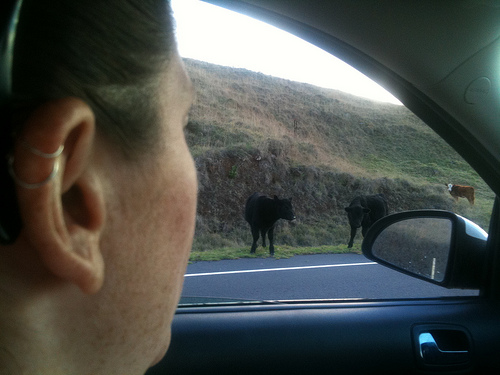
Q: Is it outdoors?
A: Yes, it is outdoors.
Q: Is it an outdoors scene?
A: Yes, it is outdoors.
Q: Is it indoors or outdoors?
A: It is outdoors.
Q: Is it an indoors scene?
A: No, it is outdoors.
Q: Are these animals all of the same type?
A: Yes, all the animals are cows.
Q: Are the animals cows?
A: Yes, all the animals are cows.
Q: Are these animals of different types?
A: No, all the animals are cows.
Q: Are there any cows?
A: Yes, there is a cow.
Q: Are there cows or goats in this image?
A: Yes, there is a cow.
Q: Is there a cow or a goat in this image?
A: Yes, there is a cow.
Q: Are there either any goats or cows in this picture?
A: Yes, there is a cow.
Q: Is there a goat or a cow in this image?
A: Yes, there is a cow.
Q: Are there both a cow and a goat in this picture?
A: No, there is a cow but no goats.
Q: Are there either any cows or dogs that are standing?
A: Yes, the cow is standing.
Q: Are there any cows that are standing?
A: Yes, there is a cow that is standing.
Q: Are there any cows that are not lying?
A: Yes, there is a cow that is standing.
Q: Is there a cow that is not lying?
A: Yes, there is a cow that is standing.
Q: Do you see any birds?
A: No, there are no birds.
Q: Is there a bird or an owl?
A: No, there are no birds or owls.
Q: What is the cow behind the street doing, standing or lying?
A: The cow is standing.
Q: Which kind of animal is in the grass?
A: The animal is a cow.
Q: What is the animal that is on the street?
A: The animal is a cow.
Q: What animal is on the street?
A: The animal is a cow.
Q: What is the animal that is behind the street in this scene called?
A: The animal is a cow.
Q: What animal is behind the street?
A: The animal is a cow.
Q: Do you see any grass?
A: Yes, there is grass.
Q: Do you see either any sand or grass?
A: Yes, there is grass.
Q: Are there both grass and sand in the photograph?
A: No, there is grass but no sand.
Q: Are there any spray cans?
A: No, there are no spray cans.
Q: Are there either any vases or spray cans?
A: No, there are no spray cans or vases.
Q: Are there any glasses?
A: No, there are no glasses.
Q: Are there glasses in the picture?
A: No, there are no glasses.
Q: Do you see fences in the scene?
A: No, there are no fences.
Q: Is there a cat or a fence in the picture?
A: No, there are no fences or cats.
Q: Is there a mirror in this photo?
A: Yes, there is a mirror.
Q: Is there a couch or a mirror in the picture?
A: Yes, there is a mirror.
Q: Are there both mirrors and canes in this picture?
A: No, there is a mirror but no canes.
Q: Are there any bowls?
A: No, there are no bowls.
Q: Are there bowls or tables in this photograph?
A: No, there are no bowls or tables.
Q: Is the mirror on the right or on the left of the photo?
A: The mirror is on the right of the image.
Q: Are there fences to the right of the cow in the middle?
A: No, there is a mirror to the right of the cow.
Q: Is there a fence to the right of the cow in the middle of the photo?
A: No, there is a mirror to the right of the cow.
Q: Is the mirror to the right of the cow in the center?
A: Yes, the mirror is to the right of the cow.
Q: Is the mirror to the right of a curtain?
A: No, the mirror is to the right of the cow.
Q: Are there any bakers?
A: No, there are no bakers.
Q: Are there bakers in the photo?
A: No, there are no bakers.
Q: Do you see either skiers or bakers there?
A: No, there are no bakers or skiers.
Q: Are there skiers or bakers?
A: No, there are no bakers or skiers.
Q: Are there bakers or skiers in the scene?
A: No, there are no bakers or skiers.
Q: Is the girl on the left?
A: Yes, the girl is on the left of the image.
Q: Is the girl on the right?
A: No, the girl is on the left of the image.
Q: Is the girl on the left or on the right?
A: The girl is on the left of the image.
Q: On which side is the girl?
A: The girl is on the left of the image.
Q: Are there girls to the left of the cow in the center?
A: Yes, there is a girl to the left of the cow.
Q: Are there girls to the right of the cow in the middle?
A: No, the girl is to the left of the cow.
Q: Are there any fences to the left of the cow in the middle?
A: No, there is a girl to the left of the cow.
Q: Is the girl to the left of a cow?
A: Yes, the girl is to the left of a cow.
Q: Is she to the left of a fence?
A: No, the girl is to the left of a cow.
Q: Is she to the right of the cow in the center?
A: No, the girl is to the left of the cow.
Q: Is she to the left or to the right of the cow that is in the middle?
A: The girl is to the left of the cow.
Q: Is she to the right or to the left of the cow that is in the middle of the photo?
A: The girl is to the left of the cow.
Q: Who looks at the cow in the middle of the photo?
A: The girl looks at the cow.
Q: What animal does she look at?
A: The girl looks at the cow.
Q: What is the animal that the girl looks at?
A: The animal is a cow.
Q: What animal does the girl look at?
A: The girl looks at the cow.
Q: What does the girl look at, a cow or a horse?
A: The girl looks at a cow.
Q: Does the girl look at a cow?
A: Yes, the girl looks at a cow.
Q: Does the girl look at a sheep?
A: No, the girl looks at a cow.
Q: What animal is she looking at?
A: The girl is looking at the cow.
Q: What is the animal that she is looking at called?
A: The animal is a cow.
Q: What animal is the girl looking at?
A: The girl is looking at the cow.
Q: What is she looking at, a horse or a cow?
A: The girl is looking at a cow.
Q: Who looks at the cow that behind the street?
A: The girl looks at the cow.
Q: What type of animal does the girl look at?
A: The girl looks at the cow.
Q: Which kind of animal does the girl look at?
A: The girl looks at the cow.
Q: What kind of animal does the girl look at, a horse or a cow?
A: The girl looks at a cow.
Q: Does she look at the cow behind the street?
A: Yes, the girl looks at the cow.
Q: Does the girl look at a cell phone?
A: No, the girl looks at the cow.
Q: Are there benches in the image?
A: No, there are no benches.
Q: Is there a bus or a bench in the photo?
A: No, there are no benches or buses.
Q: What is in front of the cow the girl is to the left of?
A: The street is in front of the cow.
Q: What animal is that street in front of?
A: The street is in front of the cow.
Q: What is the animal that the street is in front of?
A: The animal is a cow.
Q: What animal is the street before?
A: The street is in front of the cow.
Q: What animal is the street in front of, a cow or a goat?
A: The street is in front of a cow.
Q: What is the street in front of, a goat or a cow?
A: The street is in front of a cow.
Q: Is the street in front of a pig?
A: No, the street is in front of the cow.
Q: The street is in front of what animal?
A: The street is in front of the cow.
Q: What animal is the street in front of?
A: The street is in front of the cow.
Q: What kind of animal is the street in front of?
A: The street is in front of the cow.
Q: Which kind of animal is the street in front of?
A: The street is in front of the cow.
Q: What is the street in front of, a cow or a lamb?
A: The street is in front of a cow.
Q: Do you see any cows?
A: Yes, there is a cow.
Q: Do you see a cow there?
A: Yes, there is a cow.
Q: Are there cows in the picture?
A: Yes, there is a cow.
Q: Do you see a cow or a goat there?
A: Yes, there is a cow.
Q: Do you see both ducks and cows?
A: No, there is a cow but no ducks.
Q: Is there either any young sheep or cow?
A: Yes, there is a young cow.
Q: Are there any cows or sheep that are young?
A: Yes, the cow is young.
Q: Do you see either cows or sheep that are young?
A: Yes, the cow is young.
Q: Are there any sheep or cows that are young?
A: Yes, the cow is young.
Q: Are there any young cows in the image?
A: Yes, there is a young cow.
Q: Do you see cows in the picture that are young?
A: Yes, there is a cow that is young.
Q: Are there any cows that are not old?
A: Yes, there is an young cow.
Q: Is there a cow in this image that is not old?
A: Yes, there is an young cow.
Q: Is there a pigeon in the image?
A: No, there are no pigeons.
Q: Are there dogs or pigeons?
A: No, there are no pigeons or dogs.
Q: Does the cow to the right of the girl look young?
A: Yes, the cow is young.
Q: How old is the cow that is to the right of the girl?
A: The cow is young.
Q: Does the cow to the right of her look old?
A: No, the cow is young.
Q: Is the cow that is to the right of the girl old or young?
A: The cow is young.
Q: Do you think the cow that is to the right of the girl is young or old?
A: The cow is young.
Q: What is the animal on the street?
A: The animal is a cow.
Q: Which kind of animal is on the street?
A: The animal is a cow.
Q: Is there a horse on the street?
A: No, there is a cow on the street.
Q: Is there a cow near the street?
A: Yes, there is a cow near the street.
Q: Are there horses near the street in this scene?
A: No, there is a cow near the street.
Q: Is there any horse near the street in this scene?
A: No, there is a cow near the street.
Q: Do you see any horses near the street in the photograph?
A: No, there is a cow near the street.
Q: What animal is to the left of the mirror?
A: The animal is a cow.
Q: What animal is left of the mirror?
A: The animal is a cow.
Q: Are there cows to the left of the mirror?
A: Yes, there is a cow to the left of the mirror.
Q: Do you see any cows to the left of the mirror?
A: Yes, there is a cow to the left of the mirror.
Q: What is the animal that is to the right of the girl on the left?
A: The animal is a cow.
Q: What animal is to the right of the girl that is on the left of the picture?
A: The animal is a cow.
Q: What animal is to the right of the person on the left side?
A: The animal is a cow.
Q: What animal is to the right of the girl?
A: The animal is a cow.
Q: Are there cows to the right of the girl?
A: Yes, there is a cow to the right of the girl.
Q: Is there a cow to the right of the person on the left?
A: Yes, there is a cow to the right of the girl.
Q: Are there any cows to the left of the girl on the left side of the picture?
A: No, the cow is to the right of the girl.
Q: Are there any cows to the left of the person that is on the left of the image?
A: No, the cow is to the right of the girl.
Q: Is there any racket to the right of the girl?
A: No, there is a cow to the right of the girl.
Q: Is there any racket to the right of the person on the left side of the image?
A: No, there is a cow to the right of the girl.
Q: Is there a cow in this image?
A: Yes, there is a cow.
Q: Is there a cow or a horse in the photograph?
A: Yes, there is a cow.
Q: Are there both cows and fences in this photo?
A: No, there is a cow but no fences.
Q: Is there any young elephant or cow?
A: Yes, there is a young cow.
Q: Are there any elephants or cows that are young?
A: Yes, the cow is young.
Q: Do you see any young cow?
A: Yes, there is a young cow.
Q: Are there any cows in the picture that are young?
A: Yes, there is a cow that is young.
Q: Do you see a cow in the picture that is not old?
A: Yes, there is an young cow.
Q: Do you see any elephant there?
A: No, there are no elephants.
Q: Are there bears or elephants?
A: No, there are no elephants or bears.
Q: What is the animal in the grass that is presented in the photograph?
A: The animal is a cow.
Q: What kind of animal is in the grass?
A: The animal is a cow.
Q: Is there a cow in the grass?
A: Yes, there is a cow in the grass.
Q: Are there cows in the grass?
A: Yes, there is a cow in the grass.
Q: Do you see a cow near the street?
A: Yes, there is a cow near the street.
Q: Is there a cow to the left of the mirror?
A: Yes, there is a cow to the left of the mirror.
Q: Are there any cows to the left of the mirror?
A: Yes, there is a cow to the left of the mirror.